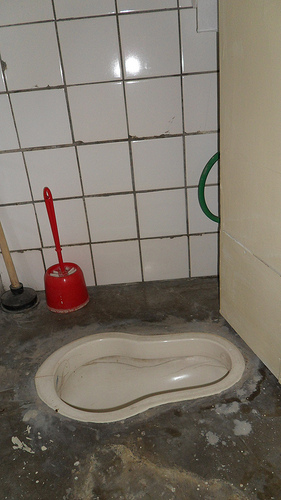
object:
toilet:
[0, 0, 281, 500]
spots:
[41, 445, 47, 450]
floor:
[1, 280, 280, 499]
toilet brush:
[42, 184, 88, 314]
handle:
[1, 230, 21, 287]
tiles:
[2, 25, 65, 92]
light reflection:
[125, 56, 141, 76]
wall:
[3, 0, 219, 305]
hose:
[198, 152, 221, 224]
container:
[44, 260, 89, 312]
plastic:
[49, 193, 52, 211]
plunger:
[1, 232, 39, 315]